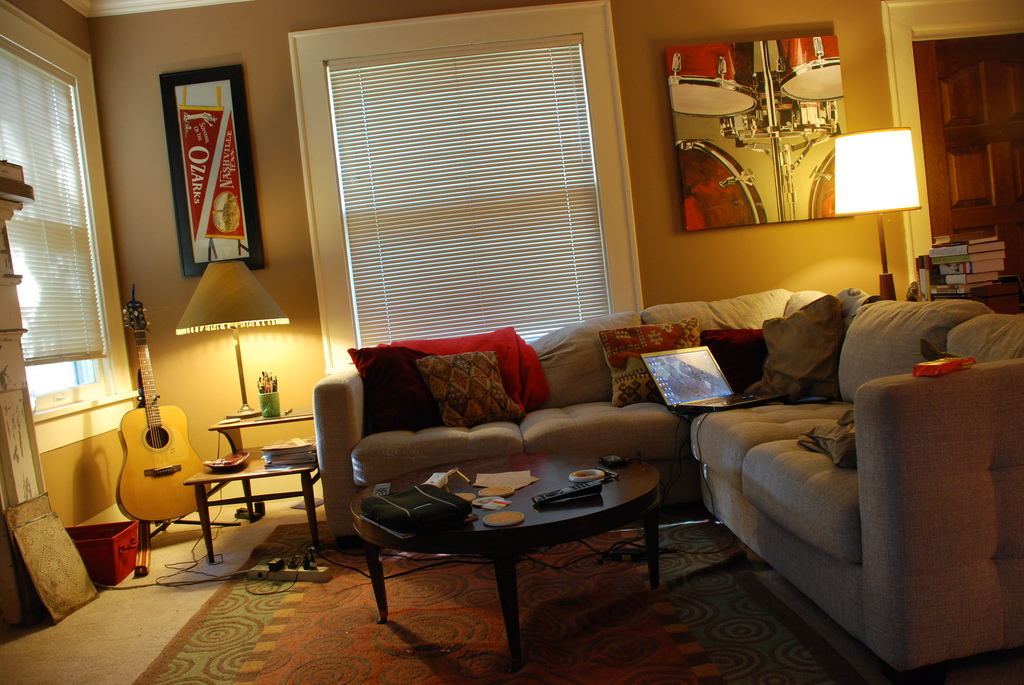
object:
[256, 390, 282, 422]
mug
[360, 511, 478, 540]
album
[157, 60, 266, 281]
picture frame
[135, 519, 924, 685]
rug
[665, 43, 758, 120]
drum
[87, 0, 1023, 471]
wall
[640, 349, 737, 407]
screen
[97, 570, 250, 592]
strip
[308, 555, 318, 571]
plugs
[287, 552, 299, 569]
plugs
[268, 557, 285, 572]
plugs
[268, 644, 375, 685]
pattern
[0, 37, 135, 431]
window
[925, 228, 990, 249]
books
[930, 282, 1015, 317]
table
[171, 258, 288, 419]
lamp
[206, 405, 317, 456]
table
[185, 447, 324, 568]
table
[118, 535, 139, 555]
handle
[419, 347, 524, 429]
pillows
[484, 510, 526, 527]
drink coaster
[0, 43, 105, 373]
miniblinds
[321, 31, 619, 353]
window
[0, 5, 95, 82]
border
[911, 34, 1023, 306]
door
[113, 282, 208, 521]
guitar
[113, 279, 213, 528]
stand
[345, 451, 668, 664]
coffee table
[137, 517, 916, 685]
carpet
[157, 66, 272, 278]
picture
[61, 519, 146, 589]
container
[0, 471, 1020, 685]
floor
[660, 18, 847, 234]
painting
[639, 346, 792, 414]
laptop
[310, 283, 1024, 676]
couch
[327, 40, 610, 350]
blinds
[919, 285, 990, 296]
books